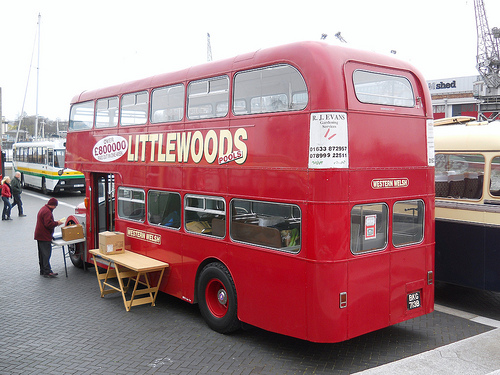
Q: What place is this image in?
A: It is at the parking lot.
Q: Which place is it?
A: It is a parking lot.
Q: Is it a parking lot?
A: Yes, it is a parking lot.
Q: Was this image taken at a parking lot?
A: Yes, it was taken in a parking lot.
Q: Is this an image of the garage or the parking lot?
A: It is showing the parking lot.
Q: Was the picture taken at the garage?
A: No, the picture was taken in the parking lot.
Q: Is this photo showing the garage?
A: No, the picture is showing the parking lot.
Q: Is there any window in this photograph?
A: Yes, there is a window.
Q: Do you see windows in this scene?
A: Yes, there is a window.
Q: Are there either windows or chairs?
A: Yes, there is a window.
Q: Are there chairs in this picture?
A: No, there are no chairs.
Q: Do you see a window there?
A: Yes, there is a window.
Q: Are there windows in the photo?
A: Yes, there is a window.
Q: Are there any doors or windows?
A: Yes, there is a window.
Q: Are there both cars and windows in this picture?
A: No, there is a window but no cars.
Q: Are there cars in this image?
A: No, there are no cars.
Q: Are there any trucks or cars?
A: No, there are no cars or trucks.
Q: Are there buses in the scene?
A: Yes, there is a bus.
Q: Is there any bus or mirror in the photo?
A: Yes, there is a bus.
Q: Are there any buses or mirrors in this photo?
A: Yes, there is a bus.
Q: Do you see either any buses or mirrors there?
A: Yes, there is a bus.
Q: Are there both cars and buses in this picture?
A: No, there is a bus but no cars.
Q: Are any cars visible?
A: No, there are no cars.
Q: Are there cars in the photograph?
A: No, there are no cars.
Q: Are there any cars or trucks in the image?
A: No, there are no cars or trucks.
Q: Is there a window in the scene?
A: Yes, there is a window.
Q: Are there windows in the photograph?
A: Yes, there is a window.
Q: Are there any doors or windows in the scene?
A: Yes, there is a window.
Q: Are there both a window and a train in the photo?
A: No, there is a window but no trains.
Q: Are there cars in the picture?
A: No, there are no cars.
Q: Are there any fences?
A: No, there are no fences.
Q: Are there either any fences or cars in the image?
A: No, there are no fences or cars.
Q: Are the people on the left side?
A: Yes, the people are on the left of the image.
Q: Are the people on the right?
A: No, the people are on the left of the image.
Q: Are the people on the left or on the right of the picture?
A: The people are on the left of the image.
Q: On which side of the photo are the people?
A: The people are on the left of the image.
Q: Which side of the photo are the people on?
A: The people are on the left of the image.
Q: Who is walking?
A: The people are walking.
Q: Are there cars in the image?
A: No, there are no cars.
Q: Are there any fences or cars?
A: No, there are no cars or fences.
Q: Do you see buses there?
A: Yes, there is a bus.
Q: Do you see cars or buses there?
A: Yes, there is a bus.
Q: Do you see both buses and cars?
A: No, there is a bus but no cars.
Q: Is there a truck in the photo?
A: No, there are no trucks.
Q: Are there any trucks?
A: No, there are no trucks.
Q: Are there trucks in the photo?
A: No, there are no trucks.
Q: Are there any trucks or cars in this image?
A: No, there are no trucks or cars.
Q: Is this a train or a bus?
A: This is a bus.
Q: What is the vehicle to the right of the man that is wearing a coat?
A: The vehicle is a bus.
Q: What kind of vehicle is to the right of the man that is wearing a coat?
A: The vehicle is a bus.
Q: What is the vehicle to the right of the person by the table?
A: The vehicle is a bus.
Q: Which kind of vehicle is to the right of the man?
A: The vehicle is a bus.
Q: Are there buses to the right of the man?
A: Yes, there is a bus to the right of the man.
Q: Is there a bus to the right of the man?
A: Yes, there is a bus to the right of the man.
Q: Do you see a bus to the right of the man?
A: Yes, there is a bus to the right of the man.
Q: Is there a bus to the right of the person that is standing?
A: Yes, there is a bus to the right of the man.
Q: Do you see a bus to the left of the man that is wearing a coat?
A: No, the bus is to the right of the man.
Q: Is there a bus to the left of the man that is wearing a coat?
A: No, the bus is to the right of the man.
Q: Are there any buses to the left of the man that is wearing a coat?
A: No, the bus is to the right of the man.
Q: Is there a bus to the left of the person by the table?
A: No, the bus is to the right of the man.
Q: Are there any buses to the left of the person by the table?
A: No, the bus is to the right of the man.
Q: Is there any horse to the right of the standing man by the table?
A: No, there is a bus to the right of the man.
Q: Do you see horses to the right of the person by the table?
A: No, there is a bus to the right of the man.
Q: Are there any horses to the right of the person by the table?
A: No, there is a bus to the right of the man.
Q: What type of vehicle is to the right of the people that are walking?
A: The vehicle is a bus.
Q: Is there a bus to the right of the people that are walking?
A: Yes, there is a bus to the right of the people.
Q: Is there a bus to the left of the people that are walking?
A: No, the bus is to the right of the people.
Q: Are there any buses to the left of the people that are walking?
A: No, the bus is to the right of the people.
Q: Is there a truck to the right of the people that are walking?
A: No, there is a bus to the right of the people.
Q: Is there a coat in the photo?
A: Yes, there is a coat.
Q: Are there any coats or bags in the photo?
A: Yes, there is a coat.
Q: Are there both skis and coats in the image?
A: No, there is a coat but no skis.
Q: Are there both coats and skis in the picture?
A: No, there is a coat but no skis.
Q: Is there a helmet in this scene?
A: No, there are no helmets.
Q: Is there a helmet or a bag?
A: No, there are no helmets or bags.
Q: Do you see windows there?
A: Yes, there is a window.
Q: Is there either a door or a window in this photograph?
A: Yes, there is a window.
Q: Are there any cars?
A: No, there are no cars.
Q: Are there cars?
A: No, there are no cars.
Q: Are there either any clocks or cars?
A: No, there are no cars or clocks.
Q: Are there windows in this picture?
A: Yes, there are windows.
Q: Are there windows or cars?
A: Yes, there are windows.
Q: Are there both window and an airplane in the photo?
A: No, there are windows but no airplanes.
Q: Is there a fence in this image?
A: No, there are no fences.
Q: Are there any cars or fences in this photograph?
A: No, there are no fences or cars.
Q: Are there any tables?
A: Yes, there is a table.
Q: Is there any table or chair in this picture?
A: Yes, there is a table.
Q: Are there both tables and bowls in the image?
A: No, there is a table but no bowls.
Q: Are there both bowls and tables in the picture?
A: No, there is a table but no bowls.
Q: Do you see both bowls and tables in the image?
A: No, there is a table but no bowls.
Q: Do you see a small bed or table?
A: Yes, there is a small table.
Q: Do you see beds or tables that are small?
A: Yes, the table is small.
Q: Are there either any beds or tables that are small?
A: Yes, the table is small.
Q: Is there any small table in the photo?
A: Yes, there is a small table.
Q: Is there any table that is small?
A: Yes, there is a table that is small.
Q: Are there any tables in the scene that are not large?
A: Yes, there is a small table.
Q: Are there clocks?
A: No, there are no clocks.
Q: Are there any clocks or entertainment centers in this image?
A: No, there are no clocks or entertainment centers.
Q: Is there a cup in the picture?
A: No, there are no cups.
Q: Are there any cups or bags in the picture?
A: No, there are no cups or bags.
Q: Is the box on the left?
A: Yes, the box is on the left of the image.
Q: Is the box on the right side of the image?
A: No, the box is on the left of the image.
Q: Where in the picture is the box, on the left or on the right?
A: The box is on the left of the image.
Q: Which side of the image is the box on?
A: The box is on the left of the image.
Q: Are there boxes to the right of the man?
A: Yes, there is a box to the right of the man.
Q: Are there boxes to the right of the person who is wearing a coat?
A: Yes, there is a box to the right of the man.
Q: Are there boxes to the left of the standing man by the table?
A: No, the box is to the right of the man.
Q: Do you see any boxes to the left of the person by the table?
A: No, the box is to the right of the man.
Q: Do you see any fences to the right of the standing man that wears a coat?
A: No, there is a box to the right of the man.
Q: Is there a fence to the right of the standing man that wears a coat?
A: No, there is a box to the right of the man.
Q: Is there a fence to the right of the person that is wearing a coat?
A: No, there is a box to the right of the man.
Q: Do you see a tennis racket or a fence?
A: No, there are no fences or rackets.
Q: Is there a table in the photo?
A: Yes, there is a table.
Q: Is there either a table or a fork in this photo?
A: Yes, there is a table.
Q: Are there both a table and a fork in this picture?
A: No, there is a table but no forks.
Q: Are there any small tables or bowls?
A: Yes, there is a small table.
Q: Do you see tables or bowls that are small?
A: Yes, the table is small.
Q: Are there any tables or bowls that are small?
A: Yes, the table is small.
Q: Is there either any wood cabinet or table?
A: Yes, there is a wood table.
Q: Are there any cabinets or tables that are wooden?
A: Yes, the table is wooden.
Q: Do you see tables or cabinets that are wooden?
A: Yes, the table is wooden.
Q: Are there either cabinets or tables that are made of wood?
A: Yes, the table is made of wood.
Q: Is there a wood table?
A: Yes, there is a table that is made of wood.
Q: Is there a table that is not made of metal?
A: Yes, there is a table that is made of wood.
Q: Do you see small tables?
A: Yes, there is a small table.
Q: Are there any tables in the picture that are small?
A: Yes, there is a table that is small.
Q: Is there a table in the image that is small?
A: Yes, there is a table that is small.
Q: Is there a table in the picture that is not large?
A: Yes, there is a small table.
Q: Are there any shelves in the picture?
A: No, there are no shelves.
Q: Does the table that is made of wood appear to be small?
A: Yes, the table is small.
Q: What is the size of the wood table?
A: The table is small.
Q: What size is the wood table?
A: The table is small.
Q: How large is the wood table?
A: The table is small.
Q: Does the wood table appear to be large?
A: No, the table is small.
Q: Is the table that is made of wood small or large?
A: The table is small.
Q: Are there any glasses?
A: No, there are no glasses.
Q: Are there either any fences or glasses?
A: No, there are no glasses or fences.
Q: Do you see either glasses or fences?
A: No, there are no glasses or fences.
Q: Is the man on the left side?
A: Yes, the man is on the left of the image.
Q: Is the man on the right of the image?
A: No, the man is on the left of the image.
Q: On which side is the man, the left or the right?
A: The man is on the left of the image.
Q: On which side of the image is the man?
A: The man is on the left of the image.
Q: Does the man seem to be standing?
A: Yes, the man is standing.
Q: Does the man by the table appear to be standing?
A: Yes, the man is standing.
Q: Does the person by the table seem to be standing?
A: Yes, the man is standing.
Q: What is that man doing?
A: The man is standing.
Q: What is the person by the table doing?
A: The man is standing.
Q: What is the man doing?
A: The man is standing.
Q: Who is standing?
A: The man is standing.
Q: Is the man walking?
A: No, the man is standing.